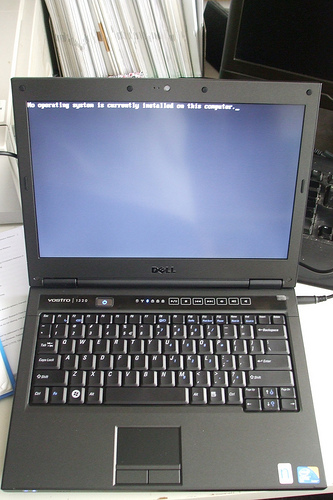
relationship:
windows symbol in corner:
[297, 463, 320, 486] [300, 79, 324, 107]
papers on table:
[1, 223, 31, 380] [0, 277, 332, 498]